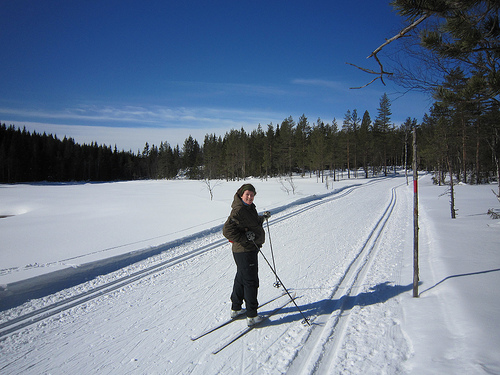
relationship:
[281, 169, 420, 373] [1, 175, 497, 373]
tracks in snow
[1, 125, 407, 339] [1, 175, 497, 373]
tracks in snow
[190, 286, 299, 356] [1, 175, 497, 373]
skis in snow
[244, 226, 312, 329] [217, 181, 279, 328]
poles on skier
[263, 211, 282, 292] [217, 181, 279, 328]
poles on skier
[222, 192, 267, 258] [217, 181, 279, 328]
jacket on skier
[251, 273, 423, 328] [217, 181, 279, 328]
shadow of skier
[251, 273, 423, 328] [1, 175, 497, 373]
shadow in snow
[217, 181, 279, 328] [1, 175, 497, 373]
skier in snow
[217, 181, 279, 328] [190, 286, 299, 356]
skier on skis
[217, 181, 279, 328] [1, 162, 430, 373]
skier on road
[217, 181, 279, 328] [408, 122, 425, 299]
skier holding pole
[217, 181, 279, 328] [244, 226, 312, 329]
skier holding poles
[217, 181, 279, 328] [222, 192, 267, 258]
skier wearing jacket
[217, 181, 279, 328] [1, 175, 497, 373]
skier on snow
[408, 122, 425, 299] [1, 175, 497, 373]
pole in snow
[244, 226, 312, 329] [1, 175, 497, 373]
poles in snow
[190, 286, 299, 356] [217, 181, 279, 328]
skis on skier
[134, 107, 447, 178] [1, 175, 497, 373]
trees in snow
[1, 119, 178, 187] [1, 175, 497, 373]
trees in snow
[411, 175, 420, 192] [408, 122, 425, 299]
tape on pole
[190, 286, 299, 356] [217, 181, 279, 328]
skis beneath skier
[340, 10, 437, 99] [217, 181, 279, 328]
branch over skier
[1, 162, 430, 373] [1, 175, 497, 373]
road in snow